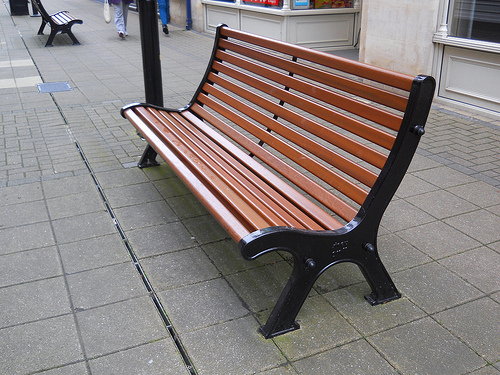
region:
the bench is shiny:
[170, 101, 407, 341]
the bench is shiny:
[145, 97, 301, 288]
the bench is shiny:
[229, 45, 333, 202]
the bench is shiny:
[206, 75, 366, 272]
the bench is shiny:
[220, 91, 278, 148]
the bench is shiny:
[246, 125, 327, 232]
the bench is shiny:
[200, 34, 258, 104]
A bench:
[21, 1, 92, 43]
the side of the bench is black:
[405, 74, 435, 166]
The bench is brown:
[182, 110, 326, 212]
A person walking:
[103, 2, 140, 44]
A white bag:
[100, 3, 120, 23]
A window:
[456, 5, 499, 42]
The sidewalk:
[13, 178, 153, 359]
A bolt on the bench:
[301, 257, 322, 272]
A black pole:
[128, 8, 181, 98]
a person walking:
[156, 4, 179, 39]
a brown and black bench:
[112, 13, 446, 339]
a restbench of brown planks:
[211, 0, 452, 168]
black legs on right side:
[252, 255, 420, 347]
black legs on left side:
[129, 135, 164, 182]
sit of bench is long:
[113, 103, 285, 269]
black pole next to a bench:
[126, 2, 176, 112]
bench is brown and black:
[29, 0, 88, 56]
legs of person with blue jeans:
[100, 0, 138, 45]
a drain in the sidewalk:
[26, 68, 79, 105]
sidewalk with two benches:
[13, 2, 455, 359]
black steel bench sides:
[236, 231, 406, 324]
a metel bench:
[64, 10, 498, 310]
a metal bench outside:
[122, 10, 467, 307]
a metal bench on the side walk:
[78, 18, 497, 268]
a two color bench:
[102, 17, 498, 370]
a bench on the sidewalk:
[44, 34, 458, 374]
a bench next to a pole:
[107, 5, 498, 365]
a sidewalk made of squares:
[4, 112, 249, 321]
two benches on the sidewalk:
[28, 9, 497, 330]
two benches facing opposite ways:
[32, 6, 497, 349]